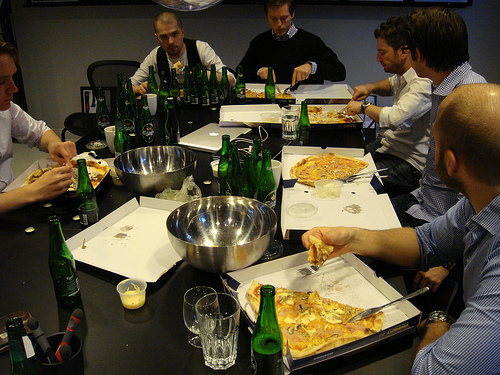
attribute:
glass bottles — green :
[38, 151, 100, 321]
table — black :
[14, 63, 444, 368]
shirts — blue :
[390, 75, 498, 355]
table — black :
[108, 47, 421, 361]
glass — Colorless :
[190, 286, 243, 370]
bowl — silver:
[164, 191, 281, 275]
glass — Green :
[188, 267, 256, 373]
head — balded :
[431, 81, 499, 210]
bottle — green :
[260, 151, 281, 213]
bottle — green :
[248, 284, 284, 373]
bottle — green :
[73, 159, 100, 224]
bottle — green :
[263, 68, 273, 98]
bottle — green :
[109, 111, 128, 149]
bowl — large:
[182, 185, 287, 296]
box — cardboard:
[399, 306, 418, 328]